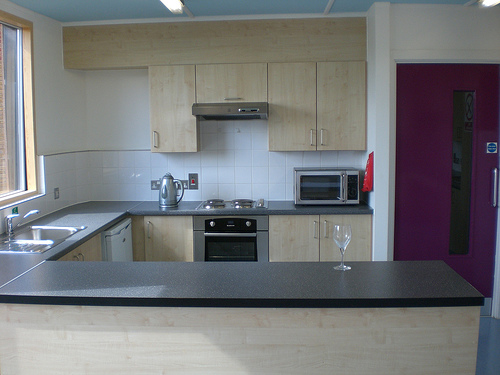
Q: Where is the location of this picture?
A: A kitchen.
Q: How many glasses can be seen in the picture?
A: 1.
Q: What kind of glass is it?
A: Wine.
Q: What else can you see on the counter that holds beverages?
A: Carafe.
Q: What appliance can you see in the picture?
A: Microwave.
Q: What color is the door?
A: Purple.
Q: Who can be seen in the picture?
A: No one.